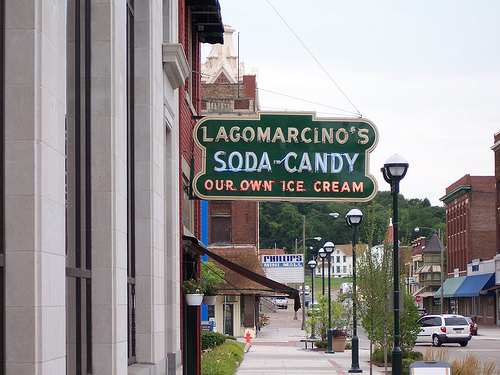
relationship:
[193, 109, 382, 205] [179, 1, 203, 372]
sign on store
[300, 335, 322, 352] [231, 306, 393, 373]
bench sitting on sidewalk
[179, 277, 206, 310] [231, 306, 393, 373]
pot hanging beside sidewalk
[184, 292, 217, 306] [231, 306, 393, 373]
pot hanging beside sidewalk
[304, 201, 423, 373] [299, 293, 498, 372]
tree beside road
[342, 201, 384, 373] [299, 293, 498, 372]
tree beside road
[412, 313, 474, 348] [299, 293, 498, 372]
car on road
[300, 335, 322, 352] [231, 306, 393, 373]
bench on sidewalk